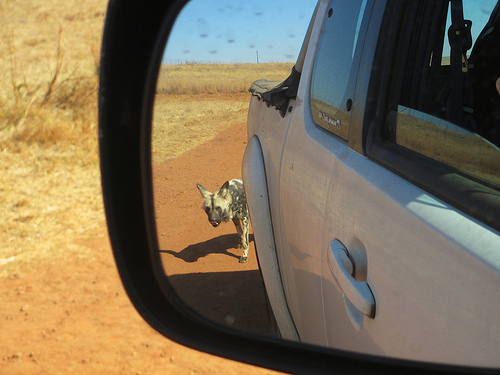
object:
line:
[207, 191, 220, 210]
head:
[191, 180, 241, 228]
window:
[396, 103, 500, 194]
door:
[274, 0, 376, 349]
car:
[235, 0, 497, 368]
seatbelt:
[445, 0, 472, 126]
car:
[231, 3, 499, 367]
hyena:
[196, 175, 266, 264]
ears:
[192, 182, 214, 201]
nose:
[210, 220, 220, 228]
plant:
[0, 24, 101, 163]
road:
[152, 104, 284, 338]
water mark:
[160, 0, 320, 100]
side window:
[308, 0, 368, 140]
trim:
[83, 0, 499, 374]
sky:
[160, 0, 324, 68]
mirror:
[144, 0, 500, 373]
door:
[316, 0, 497, 367]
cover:
[246, 65, 302, 118]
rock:
[7, 268, 21, 282]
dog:
[197, 174, 262, 264]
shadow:
[161, 232, 256, 264]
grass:
[0, 0, 108, 268]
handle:
[328, 238, 374, 316]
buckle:
[444, 19, 473, 53]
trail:
[38, 308, 76, 336]